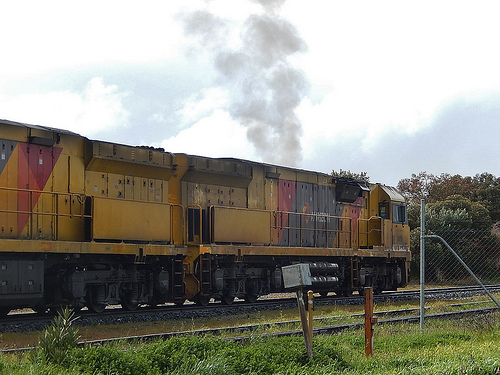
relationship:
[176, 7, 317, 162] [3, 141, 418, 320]
steam of train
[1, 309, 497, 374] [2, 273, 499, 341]
grass near tracks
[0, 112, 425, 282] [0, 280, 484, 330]
train on tracks